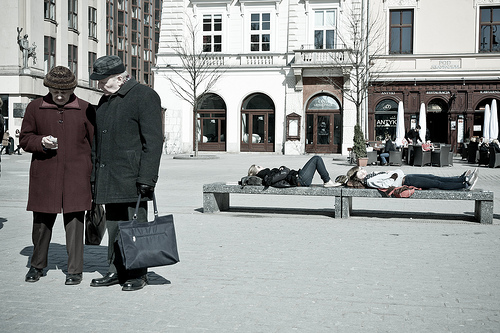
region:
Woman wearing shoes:
[22, 261, 84, 288]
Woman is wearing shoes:
[22, 263, 84, 287]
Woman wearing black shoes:
[22, 260, 84, 289]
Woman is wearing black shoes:
[21, 260, 85, 287]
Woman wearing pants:
[29, 201, 88, 274]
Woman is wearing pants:
[25, 203, 89, 278]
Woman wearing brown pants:
[27, 205, 87, 276]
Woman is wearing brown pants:
[25, 202, 91, 274]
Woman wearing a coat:
[17, 93, 97, 214]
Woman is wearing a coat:
[17, 90, 97, 216]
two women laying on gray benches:
[202, 153, 496, 222]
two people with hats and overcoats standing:
[16, 52, 180, 289]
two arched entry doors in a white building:
[188, 88, 278, 154]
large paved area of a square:
[0, 154, 496, 327]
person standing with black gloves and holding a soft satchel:
[88, 51, 183, 298]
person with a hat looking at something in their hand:
[16, 65, 93, 283]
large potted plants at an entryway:
[458, 135, 497, 170]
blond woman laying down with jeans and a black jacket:
[242, 153, 341, 185]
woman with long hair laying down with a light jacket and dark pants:
[337, 160, 484, 191]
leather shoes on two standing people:
[24, 266, 149, 290]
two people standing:
[13, 49, 185, 297]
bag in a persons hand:
[111, 176, 187, 276]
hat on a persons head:
[88, 50, 128, 83]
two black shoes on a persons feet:
[21, 258, 86, 290]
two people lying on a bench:
[194, 147, 496, 225]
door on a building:
[301, 105, 346, 158]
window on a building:
[383, 4, 419, 59]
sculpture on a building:
[13, 22, 40, 75]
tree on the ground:
[159, 10, 229, 167]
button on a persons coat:
[98, 125, 111, 137]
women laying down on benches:
[199, 100, 484, 262]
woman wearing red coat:
[22, 77, 97, 234]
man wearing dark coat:
[83, 80, 179, 217]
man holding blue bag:
[103, 175, 186, 289]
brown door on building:
[303, 90, 353, 181]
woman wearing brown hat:
[39, 60, 91, 96]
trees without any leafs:
[159, 0, 443, 187]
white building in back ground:
[140, 0, 498, 185]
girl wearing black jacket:
[243, 159, 291, 199]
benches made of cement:
[199, 150, 491, 247]